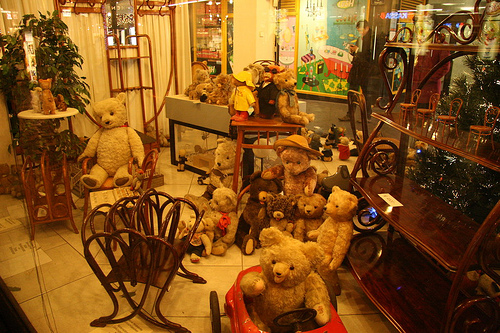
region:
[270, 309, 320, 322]
steering wheel infront of bear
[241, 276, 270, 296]
bear paw is raised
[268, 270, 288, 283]
smile on bears face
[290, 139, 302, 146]
brown hat on bear head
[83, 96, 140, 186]
big bear in chair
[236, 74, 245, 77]
bear wearing yellow hat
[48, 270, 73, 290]
beige tile on floor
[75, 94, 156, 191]
Brown sitting teddy bear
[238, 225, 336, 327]
Brown sitting Teddy bear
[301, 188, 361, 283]
Brown stuffed teddy bear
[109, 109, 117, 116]
Eye of brown bear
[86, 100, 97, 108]
Ear of brown bear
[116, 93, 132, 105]
Ear of brown bear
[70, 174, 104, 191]
Paw of teddy bear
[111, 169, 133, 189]
Paw of teddy bear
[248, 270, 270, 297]
Paw of teddy bear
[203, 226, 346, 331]
teddy bear in toy car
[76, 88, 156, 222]
teddy bear in a chair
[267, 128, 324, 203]
teddy bear wearing a hat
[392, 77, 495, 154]
little toy wooden chairs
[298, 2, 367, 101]
colorful painting on wall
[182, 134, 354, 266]
group of tan and brown teddy bears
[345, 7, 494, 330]
dark wood shelving unit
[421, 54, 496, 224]
christmas tree showing through shelving unit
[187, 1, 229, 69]
shelves in back corner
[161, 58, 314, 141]
teddy bears on a table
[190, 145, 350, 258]
a pile of teddy bears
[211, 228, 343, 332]
the bear is in a red car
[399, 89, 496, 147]
four chair figurines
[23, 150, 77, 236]
a wood magazine rack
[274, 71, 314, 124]
teddy bear sitting on the table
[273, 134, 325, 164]
a hat on the bear's head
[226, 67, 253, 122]
a bear with a rain coat on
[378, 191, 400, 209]
small paper on the shelf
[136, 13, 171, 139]
white hanging curtains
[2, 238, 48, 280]
sheets of paper on the ground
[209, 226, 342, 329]
stuffed bear in a red toy car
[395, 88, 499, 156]
four miniature chairs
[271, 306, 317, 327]
steering wheel of a toy car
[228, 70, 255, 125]
stuffed bear wearing a rain jacket and red boots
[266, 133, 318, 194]
brown stuffed bear wearing a hat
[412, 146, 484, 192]
Christmas tree behind the brown shelf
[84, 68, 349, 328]
group of stuffed bears in a store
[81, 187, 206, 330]
brown wicker rack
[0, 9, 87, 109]
green leaves of a plant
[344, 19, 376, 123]
man standing outside the store window